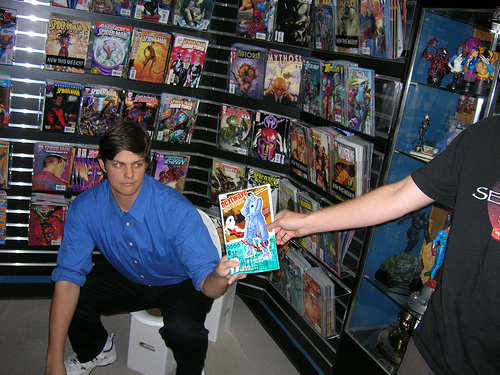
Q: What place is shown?
A: It is a display.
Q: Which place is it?
A: It is a display.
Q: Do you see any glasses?
A: No, there are no glasses.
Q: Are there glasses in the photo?
A: No, there are no glasses.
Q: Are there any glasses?
A: No, there are no glasses.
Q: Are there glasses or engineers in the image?
A: No, there are no glasses or engineers.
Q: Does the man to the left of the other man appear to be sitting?
A: Yes, the man is sitting.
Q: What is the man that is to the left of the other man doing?
A: The man is sitting.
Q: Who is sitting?
A: The man is sitting.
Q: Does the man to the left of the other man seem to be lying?
A: No, the man is sitting.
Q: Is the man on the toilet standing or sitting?
A: The man is sitting.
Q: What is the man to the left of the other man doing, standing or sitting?
A: The man is sitting.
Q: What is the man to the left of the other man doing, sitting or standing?
A: The man is sitting.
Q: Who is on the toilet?
A: The man is on the toilet.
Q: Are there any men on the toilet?
A: Yes, there is a man on the toilet.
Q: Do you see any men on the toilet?
A: Yes, there is a man on the toilet.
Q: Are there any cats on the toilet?
A: No, there is a man on the toilet.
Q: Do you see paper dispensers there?
A: No, there are no paper dispensers.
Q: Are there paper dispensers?
A: No, there are no paper dispensers.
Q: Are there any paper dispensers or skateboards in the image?
A: No, there are no paper dispensers or skateboards.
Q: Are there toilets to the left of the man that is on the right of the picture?
A: Yes, there is a toilet to the left of the man.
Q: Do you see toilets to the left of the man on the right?
A: Yes, there is a toilet to the left of the man.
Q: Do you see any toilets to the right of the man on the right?
A: No, the toilet is to the left of the man.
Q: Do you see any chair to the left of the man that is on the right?
A: No, there is a toilet to the left of the man.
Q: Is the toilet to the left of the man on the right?
A: Yes, the toilet is to the left of the man.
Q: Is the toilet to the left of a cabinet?
A: No, the toilet is to the left of the man.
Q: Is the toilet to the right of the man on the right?
A: No, the toilet is to the left of the man.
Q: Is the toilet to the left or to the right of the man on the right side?
A: The toilet is to the left of the man.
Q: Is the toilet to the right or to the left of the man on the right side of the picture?
A: The toilet is to the left of the man.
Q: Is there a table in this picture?
A: No, there are no tables.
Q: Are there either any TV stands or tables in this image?
A: No, there are no tables or TV stands.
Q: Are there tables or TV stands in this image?
A: No, there are no tables or TV stands.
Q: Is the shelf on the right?
A: Yes, the shelf is on the right of the image.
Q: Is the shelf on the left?
A: No, the shelf is on the right of the image.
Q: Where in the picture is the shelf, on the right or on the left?
A: The shelf is on the right of the image.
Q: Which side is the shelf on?
A: The shelf is on the right of the image.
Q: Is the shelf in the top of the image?
A: Yes, the shelf is in the top of the image.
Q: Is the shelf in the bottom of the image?
A: No, the shelf is in the top of the image.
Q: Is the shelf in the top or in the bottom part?
A: The shelf is in the top of the image.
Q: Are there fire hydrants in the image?
A: No, there are no fire hydrants.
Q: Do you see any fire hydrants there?
A: No, there are no fire hydrants.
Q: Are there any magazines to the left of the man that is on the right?
A: Yes, there are magazines to the left of the man.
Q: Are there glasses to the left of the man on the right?
A: No, there are magazines to the left of the man.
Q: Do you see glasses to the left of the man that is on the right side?
A: No, there are magazines to the left of the man.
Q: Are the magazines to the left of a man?
A: Yes, the magazines are to the left of a man.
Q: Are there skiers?
A: No, there are no skiers.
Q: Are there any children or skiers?
A: No, there are no skiers or children.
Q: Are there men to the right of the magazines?
A: Yes, there is a man to the right of the magazines.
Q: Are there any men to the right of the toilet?
A: Yes, there is a man to the right of the toilet.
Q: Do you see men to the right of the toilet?
A: Yes, there is a man to the right of the toilet.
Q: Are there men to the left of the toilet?
A: No, the man is to the right of the toilet.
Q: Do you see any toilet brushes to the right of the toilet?
A: No, there is a man to the right of the toilet.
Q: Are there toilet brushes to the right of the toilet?
A: No, there is a man to the right of the toilet.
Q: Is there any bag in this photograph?
A: No, there are no bags.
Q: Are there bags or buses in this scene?
A: No, there are no bags or buses.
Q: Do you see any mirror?
A: No, there are no mirrors.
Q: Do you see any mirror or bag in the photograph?
A: No, there are no mirrors or bags.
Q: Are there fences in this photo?
A: No, there are no fences.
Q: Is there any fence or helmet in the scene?
A: No, there are no fences or helmets.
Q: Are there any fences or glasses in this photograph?
A: No, there are no fences or glasses.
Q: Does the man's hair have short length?
A: Yes, the hair is short.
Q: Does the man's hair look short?
A: Yes, the hair is short.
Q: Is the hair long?
A: No, the hair is short.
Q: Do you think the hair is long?
A: No, the hair is short.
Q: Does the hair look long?
A: No, the hair is short.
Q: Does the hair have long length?
A: No, the hair is short.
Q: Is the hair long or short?
A: The hair is short.